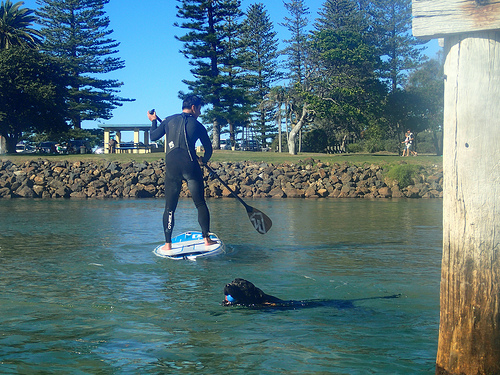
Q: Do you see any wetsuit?
A: Yes, there is a wetsuit.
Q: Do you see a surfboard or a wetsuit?
A: Yes, there is a wetsuit.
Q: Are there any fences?
A: No, there are no fences.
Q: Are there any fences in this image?
A: No, there are no fences.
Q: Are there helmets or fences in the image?
A: No, there are no fences or helmets.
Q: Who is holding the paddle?
A: The man is holding the paddle.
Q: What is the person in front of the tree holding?
A: The man is holding the paddle.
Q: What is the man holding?
A: The man is holding the paddle.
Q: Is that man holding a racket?
A: No, the man is holding the paddle.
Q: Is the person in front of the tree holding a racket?
A: No, the man is holding the paddle.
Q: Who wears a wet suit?
A: The man wears a wet suit.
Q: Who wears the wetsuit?
A: The man wears a wet suit.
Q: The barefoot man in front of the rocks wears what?
A: The man wears a wetsuit.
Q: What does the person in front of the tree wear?
A: The man wears a wetsuit.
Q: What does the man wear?
A: The man wears a wetsuit.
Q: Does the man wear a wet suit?
A: Yes, the man wears a wet suit.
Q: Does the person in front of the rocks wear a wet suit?
A: Yes, the man wears a wet suit.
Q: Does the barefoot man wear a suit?
A: No, the man wears a wet suit.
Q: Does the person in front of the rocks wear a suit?
A: No, the man wears a wet suit.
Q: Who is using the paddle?
A: The man is using the paddle.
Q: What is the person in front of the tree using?
A: The man is using a paddle.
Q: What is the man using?
A: The man is using a paddle.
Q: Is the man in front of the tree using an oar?
A: Yes, the man is using an oar.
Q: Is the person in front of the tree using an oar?
A: Yes, the man is using an oar.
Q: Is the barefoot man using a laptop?
A: No, the man is using an oar.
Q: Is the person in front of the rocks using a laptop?
A: No, the man is using an oar.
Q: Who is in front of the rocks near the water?
A: The man is in front of the rocks.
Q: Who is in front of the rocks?
A: The man is in front of the rocks.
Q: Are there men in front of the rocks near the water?
A: Yes, there is a man in front of the rocks.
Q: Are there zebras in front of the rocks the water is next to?
A: No, there is a man in front of the rocks.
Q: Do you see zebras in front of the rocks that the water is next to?
A: No, there is a man in front of the rocks.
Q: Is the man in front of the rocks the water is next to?
A: Yes, the man is in front of the rocks.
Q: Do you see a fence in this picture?
A: No, there are no fences.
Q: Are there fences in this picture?
A: No, there are no fences.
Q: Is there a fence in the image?
A: No, there are no fences.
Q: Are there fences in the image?
A: No, there are no fences.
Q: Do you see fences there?
A: No, there are no fences.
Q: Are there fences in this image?
A: No, there are no fences.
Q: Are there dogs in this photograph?
A: Yes, there is a dog.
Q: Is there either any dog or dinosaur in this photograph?
A: Yes, there is a dog.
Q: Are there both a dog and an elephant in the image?
A: No, there is a dog but no elephants.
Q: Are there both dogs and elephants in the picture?
A: No, there is a dog but no elephants.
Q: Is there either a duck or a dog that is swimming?
A: Yes, the dog is swimming.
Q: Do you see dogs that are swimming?
A: Yes, there is a dog that is swimming.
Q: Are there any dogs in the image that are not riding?
A: Yes, there is a dog that is swimming.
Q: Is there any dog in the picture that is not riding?
A: Yes, there is a dog that is swimming.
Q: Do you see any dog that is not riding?
A: Yes, there is a dog that is swimming .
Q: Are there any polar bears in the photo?
A: No, there are no polar bears.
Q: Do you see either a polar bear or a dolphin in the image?
A: No, there are no polar bears or dolphins.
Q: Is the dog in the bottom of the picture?
A: Yes, the dog is in the bottom of the image.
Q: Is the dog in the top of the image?
A: No, the dog is in the bottom of the image.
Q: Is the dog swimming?
A: Yes, the dog is swimming.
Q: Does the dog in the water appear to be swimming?
A: Yes, the dog is swimming.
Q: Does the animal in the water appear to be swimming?
A: Yes, the dog is swimming.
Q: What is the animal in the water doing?
A: The dog is swimming.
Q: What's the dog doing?
A: The dog is swimming.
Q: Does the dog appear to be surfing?
A: No, the dog is swimming.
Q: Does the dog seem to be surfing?
A: No, the dog is swimming.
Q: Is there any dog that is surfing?
A: No, there is a dog but it is swimming.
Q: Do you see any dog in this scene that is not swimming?
A: No, there is a dog but it is swimming.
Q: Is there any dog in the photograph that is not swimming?
A: No, there is a dog but it is swimming.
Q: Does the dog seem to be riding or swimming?
A: The dog is swimming.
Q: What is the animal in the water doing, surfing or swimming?
A: The dog is swimming.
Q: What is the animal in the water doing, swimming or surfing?
A: The dog is swimming.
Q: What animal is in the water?
A: The dog is in the water.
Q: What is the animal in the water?
A: The animal is a dog.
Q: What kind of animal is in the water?
A: The animal is a dog.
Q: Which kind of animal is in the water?
A: The animal is a dog.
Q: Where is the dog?
A: The dog is in the water.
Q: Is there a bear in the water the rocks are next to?
A: No, there is a dog in the water.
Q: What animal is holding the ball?
A: The dog is holding the ball.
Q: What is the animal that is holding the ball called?
A: The animal is a dog.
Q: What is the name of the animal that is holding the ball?
A: The animal is a dog.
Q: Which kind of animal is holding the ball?
A: The animal is a dog.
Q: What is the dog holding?
A: The dog is holding the ball.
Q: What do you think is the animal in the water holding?
A: The dog is holding the ball.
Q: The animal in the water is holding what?
A: The dog is holding the ball.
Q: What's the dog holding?
A: The dog is holding the ball.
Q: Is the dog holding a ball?
A: Yes, the dog is holding a ball.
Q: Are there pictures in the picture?
A: No, there are no pictures.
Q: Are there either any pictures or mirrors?
A: No, there are no pictures or mirrors.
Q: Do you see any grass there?
A: Yes, there is grass.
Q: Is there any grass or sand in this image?
A: Yes, there is grass.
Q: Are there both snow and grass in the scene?
A: No, there is grass but no snow.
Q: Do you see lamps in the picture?
A: No, there are no lamps.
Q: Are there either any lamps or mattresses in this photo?
A: No, there are no lamps or mattresses.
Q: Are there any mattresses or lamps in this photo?
A: No, there are no lamps or mattresses.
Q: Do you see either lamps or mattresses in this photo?
A: No, there are no lamps or mattresses.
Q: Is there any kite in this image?
A: No, there are no kites.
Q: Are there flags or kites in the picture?
A: No, there are no kites or flags.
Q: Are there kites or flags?
A: No, there are no kites or flags.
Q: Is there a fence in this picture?
A: No, there are no fences.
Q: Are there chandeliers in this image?
A: No, there are no chandeliers.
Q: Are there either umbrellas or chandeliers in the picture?
A: No, there are no chandeliers or umbrellas.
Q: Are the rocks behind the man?
A: Yes, the rocks are behind the man.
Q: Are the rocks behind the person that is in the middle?
A: Yes, the rocks are behind the man.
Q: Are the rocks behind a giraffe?
A: No, the rocks are behind the man.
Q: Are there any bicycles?
A: No, there are no bicycles.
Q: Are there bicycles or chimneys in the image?
A: No, there are no bicycles or chimneys.